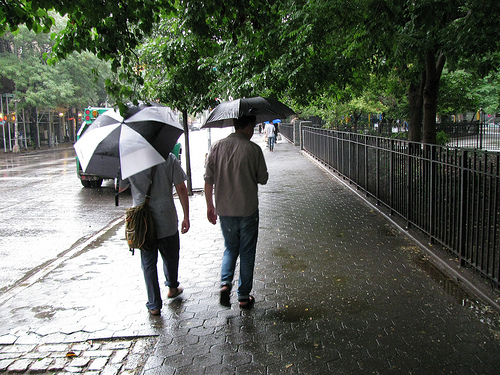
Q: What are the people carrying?
A: Umbrellas.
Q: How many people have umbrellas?
A: Two.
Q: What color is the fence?
A: Black.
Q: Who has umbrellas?
A: Two people.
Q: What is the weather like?
A: Rainy.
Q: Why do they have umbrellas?
A: It is raining.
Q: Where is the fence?
A: To the right.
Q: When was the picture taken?
A: Daytime.